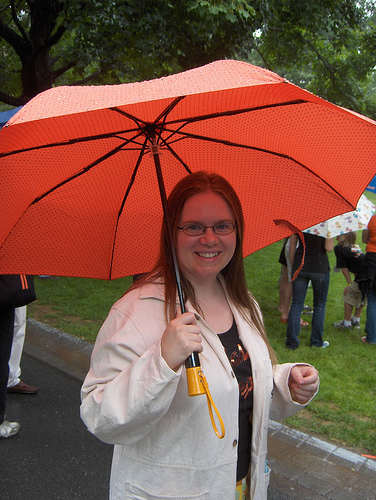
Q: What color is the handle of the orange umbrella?
A: Yellow.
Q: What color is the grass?
A: Green.